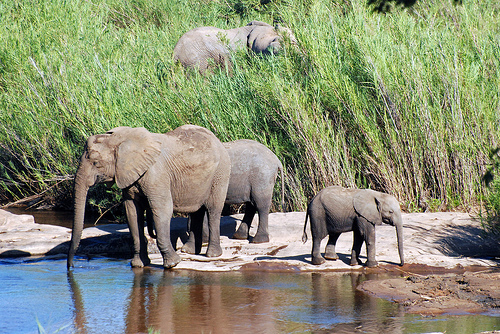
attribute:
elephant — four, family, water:
[61, 17, 420, 285]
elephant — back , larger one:
[225, 133, 288, 255]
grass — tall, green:
[5, 8, 500, 226]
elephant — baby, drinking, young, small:
[295, 174, 416, 282]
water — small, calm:
[9, 251, 496, 333]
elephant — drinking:
[49, 115, 242, 271]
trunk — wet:
[50, 169, 100, 266]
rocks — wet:
[352, 246, 499, 322]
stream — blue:
[1, 237, 293, 333]